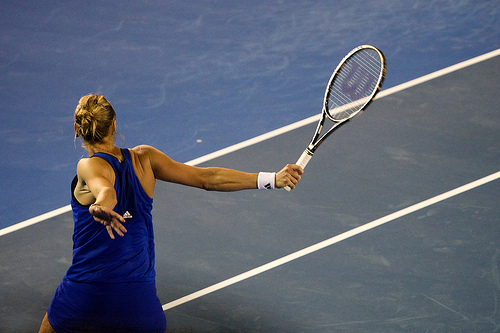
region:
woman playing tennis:
[51, 36, 408, 243]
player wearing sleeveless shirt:
[65, 128, 180, 250]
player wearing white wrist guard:
[237, 144, 313, 206]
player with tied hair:
[60, 87, 125, 149]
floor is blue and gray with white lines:
[401, 7, 495, 324]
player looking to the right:
[48, 86, 247, 326]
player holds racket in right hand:
[22, 30, 453, 320]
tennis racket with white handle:
[261, 29, 418, 210]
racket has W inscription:
[288, 32, 401, 149]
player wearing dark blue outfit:
[45, 139, 172, 331]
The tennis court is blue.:
[115, 13, 260, 94]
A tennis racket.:
[270, 27, 390, 212]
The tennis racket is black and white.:
[282, 34, 397, 200]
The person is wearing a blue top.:
[45, 145, 180, 276]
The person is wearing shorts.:
[35, 265, 185, 327]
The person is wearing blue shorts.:
[36, 266, 191, 327]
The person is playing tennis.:
[40, 40, 396, 330]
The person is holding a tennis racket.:
[270, 30, 400, 212]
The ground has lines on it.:
[335, 162, 480, 247]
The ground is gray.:
[368, 246, 476, 319]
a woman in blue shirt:
[46, 37, 243, 314]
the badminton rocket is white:
[230, 22, 458, 162]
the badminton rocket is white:
[283, 41, 437, 288]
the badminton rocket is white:
[285, 37, 347, 155]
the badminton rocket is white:
[257, 74, 387, 215]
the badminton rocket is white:
[290, 34, 391, 185]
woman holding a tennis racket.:
[257, 39, 390, 199]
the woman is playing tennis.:
[31, 43, 396, 331]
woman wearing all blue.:
[42, 137, 165, 328]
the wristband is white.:
[253, 165, 275, 192]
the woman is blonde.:
[69, 87, 121, 152]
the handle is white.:
[277, 145, 313, 197]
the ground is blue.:
[3, 0, 498, 331]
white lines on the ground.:
[16, 49, 498, 331]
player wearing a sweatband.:
[251, 167, 278, 194]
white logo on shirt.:
[118, 209, 137, 225]